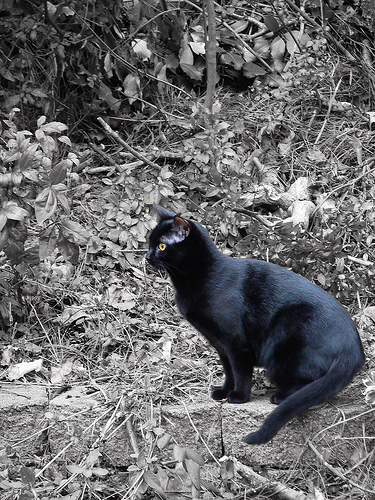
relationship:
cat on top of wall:
[138, 200, 368, 450] [2, 376, 374, 489]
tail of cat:
[238, 349, 355, 455] [138, 200, 368, 450]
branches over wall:
[116, 396, 142, 460] [2, 376, 374, 489]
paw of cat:
[226, 387, 248, 406] [138, 200, 368, 450]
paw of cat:
[210, 382, 233, 401] [138, 200, 368, 450]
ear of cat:
[154, 202, 179, 223] [138, 200, 368, 450]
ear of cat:
[166, 212, 189, 239] [138, 200, 368, 450]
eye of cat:
[154, 240, 167, 252] [138, 200, 368, 450]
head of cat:
[141, 206, 219, 288] [138, 200, 368, 450]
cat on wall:
[138, 200, 368, 450] [2, 376, 374, 489]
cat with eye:
[138, 200, 368, 450] [154, 240, 167, 252]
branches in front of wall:
[116, 396, 142, 460] [2, 376, 374, 489]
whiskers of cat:
[151, 255, 181, 276] [138, 200, 368, 450]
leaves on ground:
[119, 215, 134, 230] [1, 104, 374, 389]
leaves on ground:
[113, 297, 138, 311] [1, 104, 374, 389]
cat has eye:
[138, 200, 368, 450] [154, 240, 167, 252]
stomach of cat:
[244, 334, 291, 387] [138, 200, 368, 450]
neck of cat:
[165, 251, 225, 288] [138, 200, 368, 450]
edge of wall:
[4, 402, 374, 415] [2, 376, 374, 489]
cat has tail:
[138, 200, 368, 450] [238, 349, 355, 455]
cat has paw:
[138, 200, 368, 450] [226, 387, 248, 406]